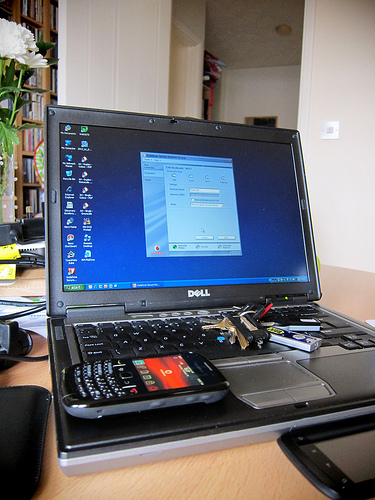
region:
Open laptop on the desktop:
[40, 100, 374, 479]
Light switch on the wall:
[317, 117, 342, 142]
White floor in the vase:
[1, 12, 61, 224]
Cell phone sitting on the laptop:
[54, 346, 235, 423]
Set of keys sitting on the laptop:
[197, 295, 281, 357]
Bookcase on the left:
[0, 1, 62, 229]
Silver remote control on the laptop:
[248, 322, 323, 354]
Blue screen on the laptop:
[56, 118, 313, 297]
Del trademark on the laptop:
[184, 286, 210, 299]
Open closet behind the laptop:
[196, 49, 231, 122]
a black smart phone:
[55, 346, 230, 420]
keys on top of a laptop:
[205, 300, 331, 363]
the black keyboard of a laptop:
[75, 303, 363, 367]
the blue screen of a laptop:
[59, 122, 308, 290]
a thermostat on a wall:
[319, 119, 340, 143]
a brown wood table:
[1, 260, 372, 496]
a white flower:
[0, 17, 46, 77]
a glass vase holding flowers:
[0, 140, 19, 227]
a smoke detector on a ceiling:
[270, 22, 295, 35]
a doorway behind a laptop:
[166, 23, 202, 125]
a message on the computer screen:
[134, 149, 241, 251]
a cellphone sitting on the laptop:
[61, 351, 223, 414]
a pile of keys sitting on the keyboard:
[205, 297, 317, 357]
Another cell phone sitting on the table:
[277, 412, 373, 488]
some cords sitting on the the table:
[2, 256, 48, 361]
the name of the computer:
[183, 288, 217, 299]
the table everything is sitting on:
[4, 272, 368, 498]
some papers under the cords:
[3, 295, 48, 337]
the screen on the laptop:
[134, 348, 203, 389]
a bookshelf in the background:
[15, 124, 48, 219]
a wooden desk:
[0, 263, 373, 498]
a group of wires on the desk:
[0, 251, 48, 361]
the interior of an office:
[0, 0, 373, 499]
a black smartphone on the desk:
[276, 411, 374, 499]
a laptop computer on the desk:
[43, 103, 373, 476]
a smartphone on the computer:
[58, 351, 228, 419]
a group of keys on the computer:
[199, 300, 322, 351]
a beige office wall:
[304, 0, 374, 273]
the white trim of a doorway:
[296, 0, 315, 165]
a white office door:
[57, 0, 171, 116]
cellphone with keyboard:
[59, 350, 229, 420]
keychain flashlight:
[262, 325, 320, 351]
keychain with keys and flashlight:
[200, 302, 320, 351]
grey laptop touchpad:
[215, 361, 318, 391]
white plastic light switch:
[322, 120, 339, 140]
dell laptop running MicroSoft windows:
[43, 105, 373, 477]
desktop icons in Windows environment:
[57, 121, 98, 281]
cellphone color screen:
[130, 353, 206, 396]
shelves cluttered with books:
[202, 49, 219, 118]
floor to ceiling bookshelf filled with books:
[0, 0, 58, 221]